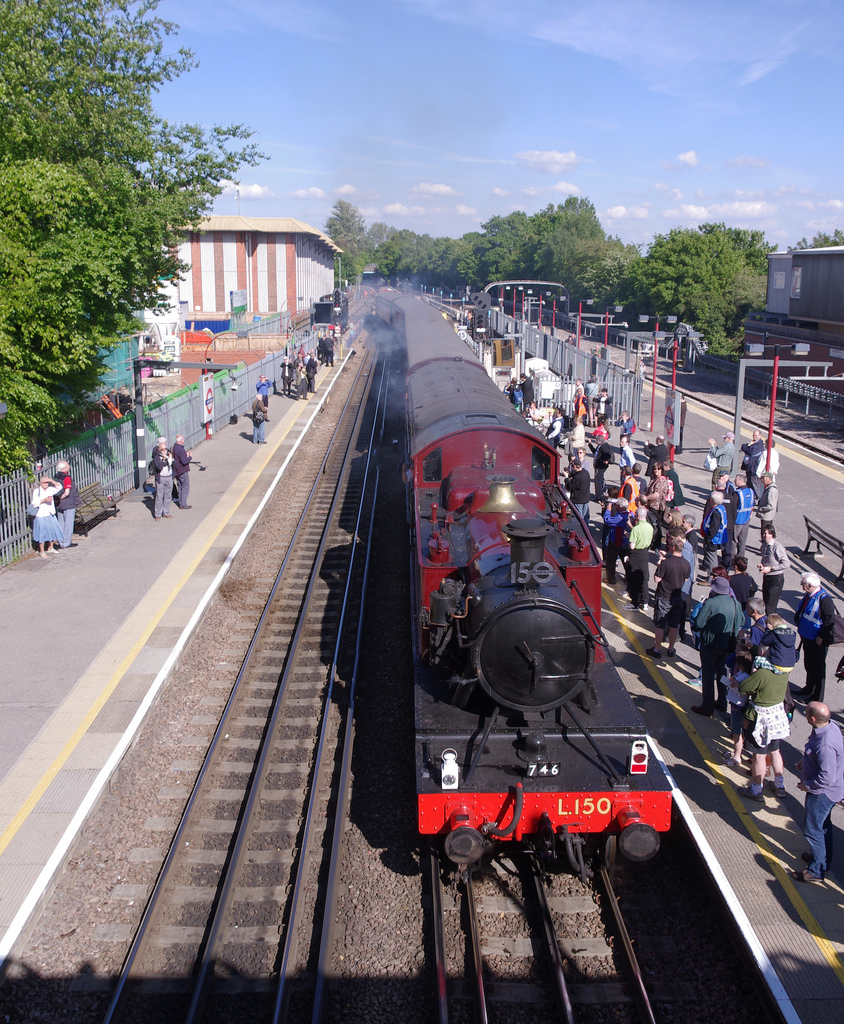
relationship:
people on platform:
[468, 253, 802, 714] [393, 220, 775, 836]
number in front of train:
[546, 768, 619, 840] [318, 213, 697, 926]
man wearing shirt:
[789, 698, 840, 882] [790, 705, 817, 772]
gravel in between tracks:
[293, 770, 501, 1013] [146, 707, 744, 972]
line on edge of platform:
[6, 346, 357, 965] [7, 348, 355, 955]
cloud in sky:
[667, 144, 709, 170] [44, 1, 841, 252]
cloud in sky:
[517, 147, 586, 176] [44, 1, 841, 252]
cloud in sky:
[662, 196, 769, 226] [44, 1, 841, 252]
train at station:
[372, 282, 674, 878] [4, 217, 841, 1021]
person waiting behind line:
[168, 431, 203, 516] [6, 349, 329, 849]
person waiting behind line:
[243, 391, 269, 443] [6, 349, 329, 849]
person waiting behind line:
[51, 458, 83, 549] [6, 349, 329, 849]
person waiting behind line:
[257, 377, 275, 421] [6, 349, 329, 849]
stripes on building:
[164, 234, 297, 323] [141, 214, 345, 316]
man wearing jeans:
[789, 698, 839, 882] [803, 791, 832, 876]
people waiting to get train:
[505, 371, 834, 883] [372, 282, 674, 878]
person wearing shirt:
[735, 646, 799, 793] [742, 664, 788, 708]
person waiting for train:
[145, 438, 181, 516] [372, 282, 674, 878]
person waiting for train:
[51, 458, 84, 550] [372, 282, 674, 878]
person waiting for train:
[26, 473, 58, 552] [372, 282, 674, 878]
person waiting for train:
[243, 391, 269, 443] [372, 282, 674, 878]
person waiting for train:
[735, 667, 799, 793] [372, 282, 674, 878]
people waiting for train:
[797, 565, 832, 710] [372, 282, 674, 878]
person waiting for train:
[687, 575, 746, 716] [372, 282, 674, 878]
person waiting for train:
[640, 537, 689, 659] [372, 282, 674, 878]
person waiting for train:
[168, 432, 203, 517] [372, 282, 674, 878]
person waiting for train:
[750, 609, 796, 676] [372, 282, 674, 878]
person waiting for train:
[798, 699, 842, 878] [372, 282, 674, 878]